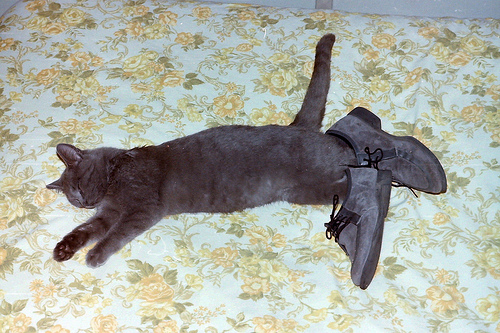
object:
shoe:
[322, 168, 393, 290]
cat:
[44, 32, 357, 269]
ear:
[54, 142, 85, 167]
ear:
[45, 178, 63, 191]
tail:
[288, 32, 337, 130]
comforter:
[0, 0, 499, 332]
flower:
[153, 69, 185, 89]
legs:
[83, 211, 148, 269]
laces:
[323, 194, 354, 244]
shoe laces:
[360, 145, 386, 172]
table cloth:
[0, 0, 499, 331]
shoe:
[324, 106, 448, 198]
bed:
[1, 0, 499, 332]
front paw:
[51, 240, 77, 263]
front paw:
[84, 248, 109, 269]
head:
[44, 143, 111, 211]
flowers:
[128, 272, 178, 305]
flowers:
[238, 275, 271, 297]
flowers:
[421, 284, 467, 313]